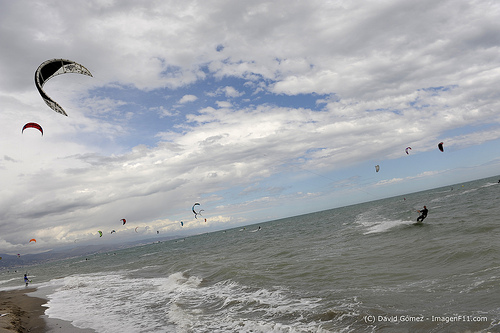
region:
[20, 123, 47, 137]
Red and black kite in the sky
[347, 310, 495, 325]
Logo of the photographer and the website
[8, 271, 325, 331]
Waves on the shore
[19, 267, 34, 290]
Person standing below the kites and the sky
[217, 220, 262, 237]
Three people out in the water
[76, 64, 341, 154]
Patch of blue sky in the clouds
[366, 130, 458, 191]
Three kites near the horizon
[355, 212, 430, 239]
Wave in front of the surfer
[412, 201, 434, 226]
Person in a wetsuit windsurfing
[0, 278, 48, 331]
Sand along the edge of the water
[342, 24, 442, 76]
the clouds in the sky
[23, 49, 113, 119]
a kite in the sky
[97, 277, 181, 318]
the water is white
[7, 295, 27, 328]
the sand is brown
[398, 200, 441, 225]
a person in the water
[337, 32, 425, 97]
the sky is cloudy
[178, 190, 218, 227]
kites in the sky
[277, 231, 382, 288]
the brown water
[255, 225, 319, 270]
the ocean water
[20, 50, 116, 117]
kite in the sky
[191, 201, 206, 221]
kite in the sky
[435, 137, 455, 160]
kite in the sky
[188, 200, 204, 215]
kite in the sky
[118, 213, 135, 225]
kite in the sky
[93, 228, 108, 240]
kite in the sky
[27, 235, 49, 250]
kite in the sky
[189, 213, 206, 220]
kite in the sky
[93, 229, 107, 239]
kite in the sky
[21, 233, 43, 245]
kite in the sky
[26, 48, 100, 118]
a windsurfing sail above the ocean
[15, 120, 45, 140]
a windsurfing sail above the ocean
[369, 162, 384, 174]
a windsurfing sail above the ocean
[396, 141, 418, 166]
a windsurfing sail above the ocean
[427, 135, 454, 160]
a windsurfing sail above the ocean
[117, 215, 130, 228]
a windsurfing sail above the ocean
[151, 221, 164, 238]
a windsurfing sail above the ocean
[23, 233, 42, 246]
a windsurfing sail above the ocean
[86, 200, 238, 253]
several windsurfing sails above the ocean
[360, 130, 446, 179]
three windsurfing sails above the ocean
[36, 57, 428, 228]
a man parasailing near the shore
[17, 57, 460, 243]
a sky filled with parasails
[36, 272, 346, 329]
waves lapping the shore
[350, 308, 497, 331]
credit for the photo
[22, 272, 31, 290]
a person on the shore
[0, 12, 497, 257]
a cloudy sky over the ocean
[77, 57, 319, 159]
blue sky showing through the clouds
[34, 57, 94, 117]
parasail filled by the wind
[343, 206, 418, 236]
the wake of the parasailer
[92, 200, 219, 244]
several parasails in the sky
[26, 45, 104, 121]
A kite in the sky.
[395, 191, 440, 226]
A person in the water.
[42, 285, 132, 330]
Waves on the sand.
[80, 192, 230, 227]
Kites in the sky.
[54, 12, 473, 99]
The sky is full of white clouds.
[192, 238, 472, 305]
The water is grayish.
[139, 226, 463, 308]
The water is rough.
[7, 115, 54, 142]
The kite is red.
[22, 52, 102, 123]
The kite is black and white.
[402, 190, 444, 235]
A person surfing in the water.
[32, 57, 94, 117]
Large black and white kite.